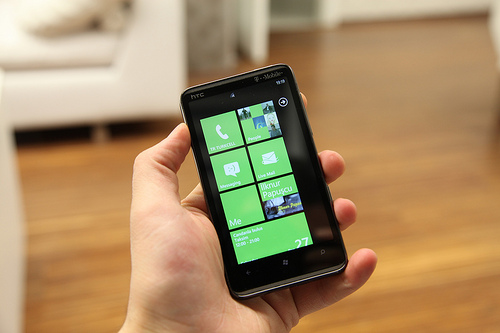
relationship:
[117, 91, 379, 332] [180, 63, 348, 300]
hand holding phone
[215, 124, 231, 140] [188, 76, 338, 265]
phone icon on top of screen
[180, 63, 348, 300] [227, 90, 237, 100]
phone has service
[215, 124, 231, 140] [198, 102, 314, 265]
phone icon on upper side of menu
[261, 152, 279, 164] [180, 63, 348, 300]
envelope showed on phone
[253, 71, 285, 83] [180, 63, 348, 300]
t-mobile writing on phone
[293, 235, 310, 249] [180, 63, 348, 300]
number at bottom of phone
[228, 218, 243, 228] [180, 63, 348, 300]
me writne on phone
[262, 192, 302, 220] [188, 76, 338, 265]
scene showed in screen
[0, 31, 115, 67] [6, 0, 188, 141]
pillow on top of couch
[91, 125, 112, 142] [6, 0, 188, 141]
leg under couch